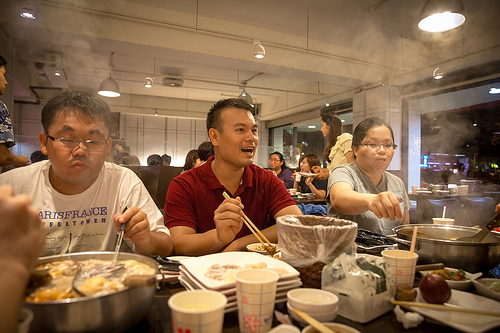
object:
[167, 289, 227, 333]
paper cup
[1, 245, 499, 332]
table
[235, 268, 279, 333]
paper cup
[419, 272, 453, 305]
apple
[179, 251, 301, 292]
plate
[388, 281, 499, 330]
plate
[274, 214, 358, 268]
plastic bag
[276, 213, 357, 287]
basket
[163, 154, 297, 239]
shirt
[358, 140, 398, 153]
glasses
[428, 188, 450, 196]
pan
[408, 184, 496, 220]
stove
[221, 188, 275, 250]
chopstick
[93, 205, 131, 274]
spoon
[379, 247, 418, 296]
paper cup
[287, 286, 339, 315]
bowl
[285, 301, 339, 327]
bowl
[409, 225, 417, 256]
straw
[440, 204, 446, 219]
straw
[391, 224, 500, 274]
pot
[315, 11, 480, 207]
steam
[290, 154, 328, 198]
woman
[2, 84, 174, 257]
person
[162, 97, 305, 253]
person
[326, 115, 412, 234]
person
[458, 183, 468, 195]
cup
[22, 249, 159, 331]
bowl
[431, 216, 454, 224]
cup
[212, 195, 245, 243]
hand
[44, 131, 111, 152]
eyeglasses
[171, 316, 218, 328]
lines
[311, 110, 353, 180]
waitress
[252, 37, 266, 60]
lighting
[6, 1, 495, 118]
ceiling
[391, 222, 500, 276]
utensil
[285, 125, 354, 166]
window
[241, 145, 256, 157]
mouth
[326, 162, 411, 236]
shirt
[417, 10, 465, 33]
light